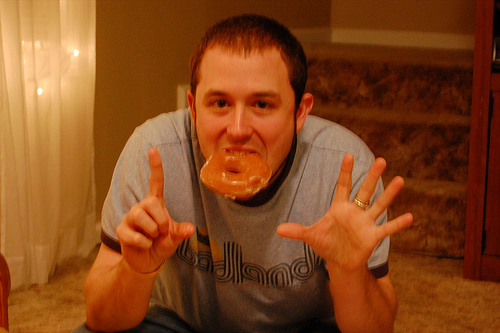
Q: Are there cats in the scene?
A: No, there are no cats.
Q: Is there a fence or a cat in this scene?
A: No, there are no cats or fences.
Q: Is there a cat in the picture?
A: No, there are no cats.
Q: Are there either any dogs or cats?
A: No, there are no cats or dogs.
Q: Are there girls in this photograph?
A: No, there are no girls.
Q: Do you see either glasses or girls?
A: No, there are no girls or glasses.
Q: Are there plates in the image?
A: No, there are no plates.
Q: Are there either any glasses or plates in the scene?
A: No, there are no plates or glasses.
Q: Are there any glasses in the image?
A: No, there are no glasses.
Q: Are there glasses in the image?
A: No, there are no glasses.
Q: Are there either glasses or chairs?
A: No, there are no glasses or chairs.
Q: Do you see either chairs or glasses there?
A: No, there are no glasses or chairs.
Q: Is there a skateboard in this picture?
A: No, there are no skateboards.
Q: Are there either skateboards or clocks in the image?
A: No, there are no skateboards or clocks.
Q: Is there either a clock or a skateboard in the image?
A: No, there are no skateboards or clocks.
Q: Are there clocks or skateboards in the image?
A: No, there are no skateboards or clocks.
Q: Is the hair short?
A: Yes, the hair is short.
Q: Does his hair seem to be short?
A: Yes, the hair is short.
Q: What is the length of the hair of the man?
A: The hair is short.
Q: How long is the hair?
A: The hair is short.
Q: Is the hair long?
A: No, the hair is short.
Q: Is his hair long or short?
A: The hair is short.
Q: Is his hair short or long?
A: The hair is short.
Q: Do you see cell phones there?
A: No, there are no cell phones.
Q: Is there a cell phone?
A: No, there are no cell phones.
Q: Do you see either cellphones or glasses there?
A: No, there are no cellphones or glasses.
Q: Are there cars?
A: No, there are no cars.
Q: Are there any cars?
A: No, there are no cars.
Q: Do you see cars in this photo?
A: No, there are no cars.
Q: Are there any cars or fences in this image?
A: No, there are no cars or fences.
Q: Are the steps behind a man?
A: Yes, the steps are behind a man.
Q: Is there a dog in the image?
A: No, there are no dogs.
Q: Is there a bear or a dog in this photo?
A: No, there are no dogs or bears.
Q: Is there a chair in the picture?
A: No, there are no chairs.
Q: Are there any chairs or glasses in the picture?
A: No, there are no chairs or glasses.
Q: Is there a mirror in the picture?
A: No, there are no mirrors.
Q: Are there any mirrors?
A: No, there are no mirrors.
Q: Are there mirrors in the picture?
A: No, there are no mirrors.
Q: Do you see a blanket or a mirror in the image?
A: No, there are no mirrors or blankets.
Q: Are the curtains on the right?
A: No, the curtains are on the left of the image.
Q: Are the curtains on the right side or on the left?
A: The curtains are on the left of the image.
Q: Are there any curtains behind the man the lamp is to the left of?
A: Yes, there are curtains behind the man.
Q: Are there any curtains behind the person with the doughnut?
A: Yes, there are curtains behind the man.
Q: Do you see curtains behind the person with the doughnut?
A: Yes, there are curtains behind the man.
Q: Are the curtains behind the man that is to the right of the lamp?
A: Yes, the curtains are behind the man.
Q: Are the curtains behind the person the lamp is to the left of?
A: Yes, the curtains are behind the man.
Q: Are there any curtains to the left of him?
A: Yes, there are curtains to the left of the man.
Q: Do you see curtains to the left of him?
A: Yes, there are curtains to the left of the man.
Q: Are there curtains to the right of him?
A: No, the curtains are to the left of the man.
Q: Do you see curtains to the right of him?
A: No, the curtains are to the left of the man.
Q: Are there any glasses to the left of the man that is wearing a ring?
A: No, there are curtains to the left of the man.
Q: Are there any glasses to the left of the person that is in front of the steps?
A: No, there are curtains to the left of the man.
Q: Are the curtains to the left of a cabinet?
A: No, the curtains are to the left of the man.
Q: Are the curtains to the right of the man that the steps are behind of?
A: No, the curtains are to the left of the man.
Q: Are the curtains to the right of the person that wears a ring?
A: No, the curtains are to the left of the man.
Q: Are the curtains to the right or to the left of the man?
A: The curtains are to the left of the man.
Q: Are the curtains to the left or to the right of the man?
A: The curtains are to the left of the man.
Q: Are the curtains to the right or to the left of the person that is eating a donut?
A: The curtains are to the left of the man.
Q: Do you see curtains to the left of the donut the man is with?
A: Yes, there are curtains to the left of the donut.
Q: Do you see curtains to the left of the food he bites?
A: Yes, there are curtains to the left of the donut.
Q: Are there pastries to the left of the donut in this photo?
A: No, there are curtains to the left of the donut.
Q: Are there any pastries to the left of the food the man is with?
A: No, there are curtains to the left of the donut.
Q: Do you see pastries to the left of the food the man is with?
A: No, there are curtains to the left of the donut.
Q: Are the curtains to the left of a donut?
A: Yes, the curtains are to the left of a donut.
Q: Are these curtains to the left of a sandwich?
A: No, the curtains are to the left of a donut.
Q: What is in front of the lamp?
A: The curtains are in front of the lamp.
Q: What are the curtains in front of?
A: The curtains are in front of the lamp.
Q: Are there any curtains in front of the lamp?
A: Yes, there are curtains in front of the lamp.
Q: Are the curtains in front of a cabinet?
A: No, the curtains are in front of the lamp.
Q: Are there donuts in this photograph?
A: Yes, there is a donut.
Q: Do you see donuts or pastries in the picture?
A: Yes, there is a donut.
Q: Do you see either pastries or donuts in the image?
A: Yes, there is a donut.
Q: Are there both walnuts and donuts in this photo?
A: No, there is a donut but no walnuts.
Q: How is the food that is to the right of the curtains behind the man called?
A: The food is a donut.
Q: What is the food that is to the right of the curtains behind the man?
A: The food is a donut.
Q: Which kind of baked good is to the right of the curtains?
A: The food is a donut.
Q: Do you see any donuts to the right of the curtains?
A: Yes, there is a donut to the right of the curtains.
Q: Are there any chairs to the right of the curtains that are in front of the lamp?
A: No, there is a donut to the right of the curtains.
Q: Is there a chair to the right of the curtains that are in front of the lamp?
A: No, there is a donut to the right of the curtains.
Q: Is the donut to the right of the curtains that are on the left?
A: Yes, the donut is to the right of the curtains.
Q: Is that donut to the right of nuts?
A: No, the donut is to the right of the curtains.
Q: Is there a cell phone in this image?
A: No, there are no cell phones.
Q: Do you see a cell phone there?
A: No, there are no cell phones.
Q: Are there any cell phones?
A: No, there are no cell phones.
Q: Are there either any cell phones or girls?
A: No, there are no cell phones or girls.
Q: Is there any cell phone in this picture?
A: No, there are no cell phones.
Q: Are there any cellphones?
A: No, there are no cellphones.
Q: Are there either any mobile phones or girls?
A: No, there are no mobile phones or girls.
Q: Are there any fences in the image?
A: No, there are no fences.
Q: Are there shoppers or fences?
A: No, there are no fences or shoppers.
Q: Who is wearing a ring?
A: The man is wearing a ring.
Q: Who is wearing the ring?
A: The man is wearing a ring.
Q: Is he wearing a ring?
A: Yes, the man is wearing a ring.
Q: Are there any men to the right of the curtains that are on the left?
A: Yes, there is a man to the right of the curtains.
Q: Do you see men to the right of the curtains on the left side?
A: Yes, there is a man to the right of the curtains.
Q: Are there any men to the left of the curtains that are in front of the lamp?
A: No, the man is to the right of the curtains.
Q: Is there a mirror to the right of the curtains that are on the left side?
A: No, there is a man to the right of the curtains.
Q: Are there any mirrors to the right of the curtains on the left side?
A: No, there is a man to the right of the curtains.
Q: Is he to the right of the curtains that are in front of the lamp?
A: Yes, the man is to the right of the curtains.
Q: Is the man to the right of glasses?
A: No, the man is to the right of the curtains.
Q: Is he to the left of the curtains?
A: No, the man is to the right of the curtains.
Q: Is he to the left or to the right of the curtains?
A: The man is to the right of the curtains.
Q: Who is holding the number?
A: The man is holding the number.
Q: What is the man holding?
A: The man is holding the number.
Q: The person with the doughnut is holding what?
A: The man is holding the number.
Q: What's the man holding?
A: The man is holding the number.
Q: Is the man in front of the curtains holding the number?
A: Yes, the man is holding the number.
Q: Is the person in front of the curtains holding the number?
A: Yes, the man is holding the number.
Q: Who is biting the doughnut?
A: The man is biting the doughnut.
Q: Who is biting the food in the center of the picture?
A: The man is biting the doughnut.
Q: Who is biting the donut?
A: The man is biting the doughnut.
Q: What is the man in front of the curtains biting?
A: The man is biting the donut.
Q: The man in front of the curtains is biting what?
A: The man is biting the donut.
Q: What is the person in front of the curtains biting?
A: The man is biting the donut.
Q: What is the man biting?
A: The man is biting the donut.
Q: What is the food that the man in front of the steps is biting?
A: The food is a donut.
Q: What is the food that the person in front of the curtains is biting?
A: The food is a donut.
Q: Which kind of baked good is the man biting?
A: The man is biting the donut.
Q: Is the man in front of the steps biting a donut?
A: Yes, the man is biting a donut.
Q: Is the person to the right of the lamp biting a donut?
A: Yes, the man is biting a donut.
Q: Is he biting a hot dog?
A: No, the man is biting a donut.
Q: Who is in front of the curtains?
A: The man is in front of the curtains.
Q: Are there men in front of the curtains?
A: Yes, there is a man in front of the curtains.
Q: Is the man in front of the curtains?
A: Yes, the man is in front of the curtains.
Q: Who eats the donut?
A: The man eats the donut.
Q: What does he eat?
A: The man eats a doughnut.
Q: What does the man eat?
A: The man eats a doughnut.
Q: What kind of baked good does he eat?
A: The man eats a doughnut.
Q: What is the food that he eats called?
A: The food is a donut.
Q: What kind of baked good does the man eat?
A: The man eats a doughnut.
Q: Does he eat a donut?
A: Yes, the man eats a donut.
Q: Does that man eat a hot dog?
A: No, the man eats a donut.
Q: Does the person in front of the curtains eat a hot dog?
A: No, the man eats a donut.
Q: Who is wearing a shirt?
A: The man is wearing a shirt.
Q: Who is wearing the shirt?
A: The man is wearing a shirt.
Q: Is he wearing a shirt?
A: Yes, the man is wearing a shirt.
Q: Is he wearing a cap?
A: No, the man is wearing a shirt.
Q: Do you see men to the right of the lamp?
A: Yes, there is a man to the right of the lamp.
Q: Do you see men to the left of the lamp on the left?
A: No, the man is to the right of the lamp.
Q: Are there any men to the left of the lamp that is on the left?
A: No, the man is to the right of the lamp.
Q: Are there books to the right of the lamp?
A: No, there is a man to the right of the lamp.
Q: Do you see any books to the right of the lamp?
A: No, there is a man to the right of the lamp.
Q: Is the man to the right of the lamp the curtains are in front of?
A: Yes, the man is to the right of the lamp.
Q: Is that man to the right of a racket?
A: No, the man is to the right of the lamp.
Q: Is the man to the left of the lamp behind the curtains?
A: No, the man is to the right of the lamp.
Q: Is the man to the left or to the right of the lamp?
A: The man is to the right of the lamp.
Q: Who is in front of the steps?
A: The man is in front of the steps.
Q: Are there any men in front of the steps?
A: Yes, there is a man in front of the steps.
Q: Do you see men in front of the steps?
A: Yes, there is a man in front of the steps.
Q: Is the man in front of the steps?
A: Yes, the man is in front of the steps.